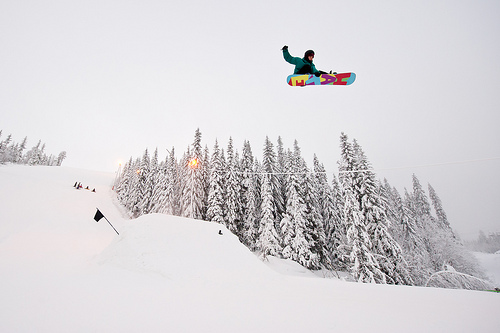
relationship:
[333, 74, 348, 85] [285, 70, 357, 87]
letter on bottom of snowboard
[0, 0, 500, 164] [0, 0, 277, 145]
clouds in sky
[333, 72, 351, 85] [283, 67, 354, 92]
letter on bottom of snowboard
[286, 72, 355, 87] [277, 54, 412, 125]
bottom of snowboard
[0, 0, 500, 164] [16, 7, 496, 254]
clouds in sky sky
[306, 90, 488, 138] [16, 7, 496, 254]
clouds in sky sky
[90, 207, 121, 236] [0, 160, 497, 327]
flag marker on ski slope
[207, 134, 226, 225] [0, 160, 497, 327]
tree on ski slope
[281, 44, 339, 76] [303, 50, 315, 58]
person wearing helmet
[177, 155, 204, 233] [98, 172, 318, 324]
light pole on ski slope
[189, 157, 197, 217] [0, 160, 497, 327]
light on ski slope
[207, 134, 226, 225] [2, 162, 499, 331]
tree lining mountainside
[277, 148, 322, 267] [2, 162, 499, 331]
tree lining mountainside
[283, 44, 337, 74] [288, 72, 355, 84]
person on snowboard